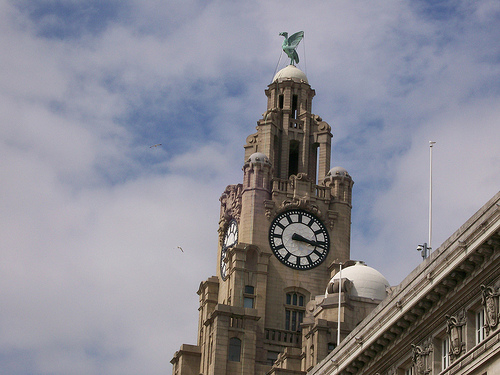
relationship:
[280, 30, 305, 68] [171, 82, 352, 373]
statue on top of clock tower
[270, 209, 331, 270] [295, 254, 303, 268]
clock with roman numerals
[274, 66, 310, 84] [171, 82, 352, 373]
dome on a clock tower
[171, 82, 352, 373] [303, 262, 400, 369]
clock tower next to a building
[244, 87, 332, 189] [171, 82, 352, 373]
pillars on clock tower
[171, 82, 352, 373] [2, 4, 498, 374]
clock tower in sky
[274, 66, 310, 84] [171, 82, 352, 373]
dome above clock tower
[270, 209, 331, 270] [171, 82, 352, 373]
clock on clock tower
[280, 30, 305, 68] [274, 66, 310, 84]
statue near dome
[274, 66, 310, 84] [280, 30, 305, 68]
dome beneath statue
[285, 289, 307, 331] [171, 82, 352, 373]
window of clock tower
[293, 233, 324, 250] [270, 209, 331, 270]
hand of clock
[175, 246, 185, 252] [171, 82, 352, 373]
bird by clock tower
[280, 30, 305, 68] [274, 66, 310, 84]
statue on dome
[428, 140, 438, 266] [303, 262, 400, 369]
lightning rod on building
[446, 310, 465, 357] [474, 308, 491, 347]
statues by windows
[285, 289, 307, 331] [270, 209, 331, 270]
window below clock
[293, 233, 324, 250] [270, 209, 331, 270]
hand on clock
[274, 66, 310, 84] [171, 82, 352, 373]
dome on clock tower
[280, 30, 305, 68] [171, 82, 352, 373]
statue on clock tower